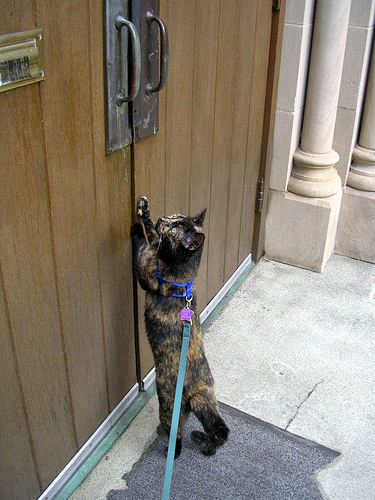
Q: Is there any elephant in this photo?
A: No, there are no elephants.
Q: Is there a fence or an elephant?
A: No, there are no elephants or fences.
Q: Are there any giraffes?
A: No, there are no giraffes.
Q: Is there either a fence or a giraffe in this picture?
A: No, there are no giraffes or fences.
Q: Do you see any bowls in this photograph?
A: No, there are no bowls.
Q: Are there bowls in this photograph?
A: No, there are no bowls.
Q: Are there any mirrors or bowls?
A: No, there are no bowls or mirrors.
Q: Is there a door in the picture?
A: Yes, there is a door.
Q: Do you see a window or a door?
A: Yes, there is a door.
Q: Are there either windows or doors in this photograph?
A: Yes, there is a door.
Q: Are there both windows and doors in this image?
A: No, there is a door but no windows.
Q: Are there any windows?
A: No, there are no windows.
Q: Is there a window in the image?
A: No, there are no windows.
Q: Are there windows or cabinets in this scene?
A: No, there are no windows or cabinets.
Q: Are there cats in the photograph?
A: Yes, there is a cat.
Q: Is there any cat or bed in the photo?
A: Yes, there is a cat.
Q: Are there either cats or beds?
A: Yes, there is a cat.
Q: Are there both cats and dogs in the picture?
A: No, there is a cat but no dogs.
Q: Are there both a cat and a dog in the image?
A: No, there is a cat but no dogs.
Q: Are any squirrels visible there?
A: No, there are no squirrels.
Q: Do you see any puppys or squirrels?
A: No, there are no squirrels or puppys.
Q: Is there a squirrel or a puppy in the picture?
A: No, there are no squirrels or puppys.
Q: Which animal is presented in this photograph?
A: The animal is a cat.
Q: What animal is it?
A: The animal is a cat.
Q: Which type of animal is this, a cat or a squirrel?
A: This is a cat.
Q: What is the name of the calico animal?
A: The animal is a cat.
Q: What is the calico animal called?
A: The animal is a cat.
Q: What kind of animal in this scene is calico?
A: The animal is a cat.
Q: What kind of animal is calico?
A: The animal is a cat.